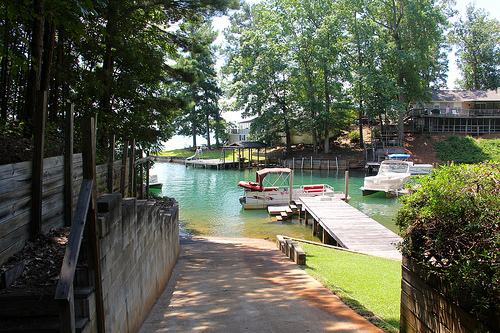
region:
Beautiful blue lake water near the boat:
[174, 171, 232, 207]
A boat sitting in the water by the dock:
[235, 164, 337, 210]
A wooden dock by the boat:
[299, 193, 411, 259]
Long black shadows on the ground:
[170, 228, 335, 330]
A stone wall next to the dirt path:
[96, 183, 188, 328]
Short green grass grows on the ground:
[337, 266, 397, 299]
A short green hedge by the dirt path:
[406, 178, 498, 296]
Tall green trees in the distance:
[242, 0, 377, 149]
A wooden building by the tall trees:
[399, 85, 496, 137]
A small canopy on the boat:
[257, 166, 295, 181]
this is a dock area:
[30, 11, 412, 284]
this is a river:
[124, 104, 404, 326]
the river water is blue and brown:
[145, 148, 273, 257]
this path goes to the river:
[179, 234, 325, 331]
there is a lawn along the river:
[309, 237, 396, 304]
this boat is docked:
[231, 168, 351, 232]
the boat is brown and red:
[220, 156, 344, 219]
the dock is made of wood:
[310, 191, 423, 294]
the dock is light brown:
[304, 191, 365, 242]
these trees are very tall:
[129, 18, 387, 128]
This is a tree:
[21, 19, 54, 269]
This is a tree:
[51, 22, 80, 233]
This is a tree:
[74, 36, 103, 230]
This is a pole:
[26, 82, 63, 270]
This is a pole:
[58, 91, 80, 235]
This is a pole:
[80, 111, 100, 238]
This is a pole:
[101, 128, 120, 204]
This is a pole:
[118, 132, 129, 209]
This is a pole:
[127, 130, 138, 211]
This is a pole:
[144, 147, 151, 213]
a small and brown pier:
[298, 187, 388, 264]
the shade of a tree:
[218, 232, 269, 304]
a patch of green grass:
[346, 250, 381, 306]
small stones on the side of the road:
[276, 231, 304, 271]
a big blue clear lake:
[182, 160, 216, 208]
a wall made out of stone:
[110, 180, 183, 284]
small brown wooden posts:
[25, 99, 105, 154]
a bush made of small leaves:
[438, 170, 495, 264]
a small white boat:
[233, 165, 304, 210]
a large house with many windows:
[413, 90, 490, 144]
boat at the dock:
[245, 160, 302, 228]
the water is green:
[188, 178, 210, 211]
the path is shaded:
[179, 253, 270, 328]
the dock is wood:
[308, 211, 370, 247]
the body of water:
[195, 187, 235, 228]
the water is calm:
[181, 180, 211, 197]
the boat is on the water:
[354, 143, 421, 196]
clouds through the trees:
[202, 36, 241, 120]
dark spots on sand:
[260, 276, 362, 321]